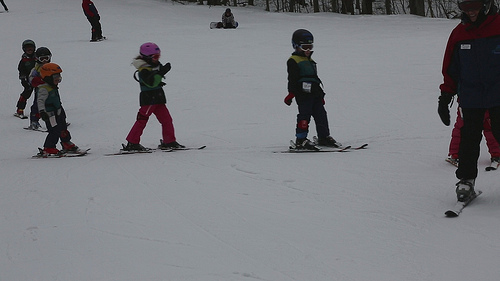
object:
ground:
[0, 1, 497, 281]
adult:
[437, 0, 500, 202]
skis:
[444, 180, 483, 217]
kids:
[22, 46, 51, 132]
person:
[221, 8, 236, 28]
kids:
[37, 63, 81, 155]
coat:
[130, 55, 172, 107]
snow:
[0, 0, 499, 280]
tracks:
[227, 161, 306, 194]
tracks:
[356, 132, 454, 143]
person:
[81, 0, 106, 42]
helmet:
[39, 63, 62, 79]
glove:
[437, 95, 454, 126]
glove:
[284, 87, 296, 106]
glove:
[159, 61, 171, 79]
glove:
[40, 109, 50, 122]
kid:
[126, 42, 186, 151]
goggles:
[296, 44, 314, 52]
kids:
[12, 39, 39, 119]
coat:
[437, 12, 499, 103]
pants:
[126, 104, 177, 145]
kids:
[284, 28, 343, 149]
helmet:
[291, 28, 315, 48]